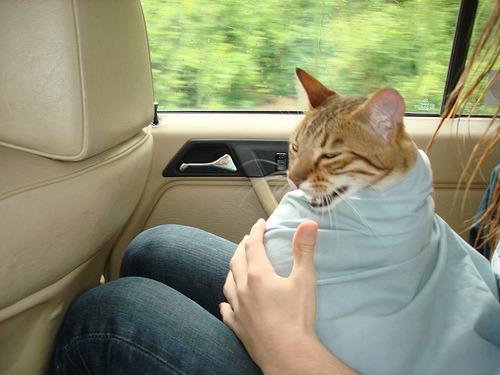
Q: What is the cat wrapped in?
A: Blue blanket.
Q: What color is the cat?
A: Light brown.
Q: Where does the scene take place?
A: Inside a car.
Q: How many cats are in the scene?
A: One.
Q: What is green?
A: Trees.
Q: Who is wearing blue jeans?
A: Person holding cat.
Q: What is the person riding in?
A: A car.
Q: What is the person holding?
A: A cat.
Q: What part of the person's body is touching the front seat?
A: The knees.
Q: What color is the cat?
A: Orange.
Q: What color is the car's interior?
A: Tan.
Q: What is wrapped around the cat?
A: Blanket.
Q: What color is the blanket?
A: Blue.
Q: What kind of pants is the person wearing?
A: Blue jeans.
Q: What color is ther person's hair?
A: Brown.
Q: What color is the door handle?
A: Silver.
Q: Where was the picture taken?
A: In a car.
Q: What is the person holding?
A: A cat.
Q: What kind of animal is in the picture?
A: A cat.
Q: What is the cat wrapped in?
A: A blanket.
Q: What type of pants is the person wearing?
A: Jeans.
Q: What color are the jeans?
A: Blue.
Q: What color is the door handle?
A: Silver.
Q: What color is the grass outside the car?
A: Green.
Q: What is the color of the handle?
A: Black.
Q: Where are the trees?
A: Outside the car.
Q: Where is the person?
A: Inside the car.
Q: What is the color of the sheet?
A: Blue.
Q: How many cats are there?
A: 1.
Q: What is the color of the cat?
A: Brown.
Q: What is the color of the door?
A: Brown.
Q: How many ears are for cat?
A: 2.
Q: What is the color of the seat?
A: Brown.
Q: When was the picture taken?
A: Daytime.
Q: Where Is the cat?
A: On the girl's lap.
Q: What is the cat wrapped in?
A: A blanket.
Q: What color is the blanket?
A: Blue.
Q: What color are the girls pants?
A: Blue.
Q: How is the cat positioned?
A: On the girl's lap.